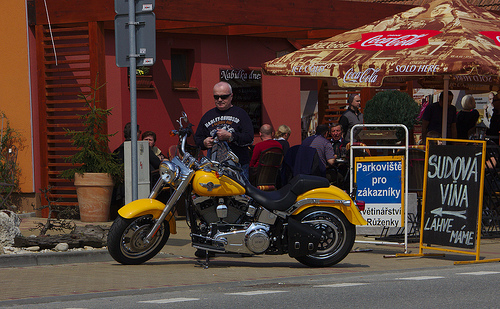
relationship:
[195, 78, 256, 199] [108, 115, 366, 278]
man standing on other side motorcycle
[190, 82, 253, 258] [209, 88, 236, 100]
man wearing sunglasses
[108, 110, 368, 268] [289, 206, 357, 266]
motorcycle has tires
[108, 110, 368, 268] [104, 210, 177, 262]
motorcycle has tires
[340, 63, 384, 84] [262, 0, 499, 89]
logo on tent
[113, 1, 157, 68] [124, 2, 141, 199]
sign's back on pole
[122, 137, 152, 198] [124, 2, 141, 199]
sign's back on pole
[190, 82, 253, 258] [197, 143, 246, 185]
man wearing pants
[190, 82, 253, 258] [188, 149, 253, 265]
man wearing pants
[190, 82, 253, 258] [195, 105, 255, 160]
man wearing shirt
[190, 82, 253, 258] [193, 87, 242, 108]
man wearing sunglasses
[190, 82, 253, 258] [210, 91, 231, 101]
man wearing sunglasses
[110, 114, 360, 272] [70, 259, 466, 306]
bike on street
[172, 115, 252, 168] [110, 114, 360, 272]
handalbars on bike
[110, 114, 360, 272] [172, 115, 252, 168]
bike has handalbars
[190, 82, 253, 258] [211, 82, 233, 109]
man has head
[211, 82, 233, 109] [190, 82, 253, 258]
head of man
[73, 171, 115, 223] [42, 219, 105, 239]
plant pot on ground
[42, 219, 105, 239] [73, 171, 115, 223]
ground has plant pot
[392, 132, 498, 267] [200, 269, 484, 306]
sign near street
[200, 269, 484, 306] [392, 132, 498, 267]
street near sign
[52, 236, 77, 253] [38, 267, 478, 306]
stone near street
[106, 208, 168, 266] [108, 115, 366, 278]
tire of motorcycle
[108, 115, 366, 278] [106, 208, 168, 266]
motorcycle has tire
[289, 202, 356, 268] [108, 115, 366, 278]
tire in back of motorcycle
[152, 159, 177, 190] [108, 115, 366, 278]
headlight in front of motorcycle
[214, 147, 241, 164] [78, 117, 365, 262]
rearview mirror on side of motorcycle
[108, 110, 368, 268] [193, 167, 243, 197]
motorcycle has tank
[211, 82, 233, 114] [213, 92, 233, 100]
face has glasses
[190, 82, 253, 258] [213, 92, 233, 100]
man has glasses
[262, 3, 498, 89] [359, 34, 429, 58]
tent has logo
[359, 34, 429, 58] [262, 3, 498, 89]
logo on tent